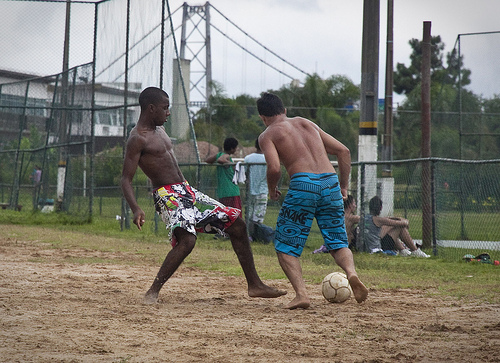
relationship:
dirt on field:
[236, 306, 345, 340] [126, 269, 368, 342]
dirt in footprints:
[236, 306, 345, 340] [273, 285, 321, 328]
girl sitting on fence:
[22, 160, 57, 212] [2, 56, 113, 191]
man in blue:
[243, 44, 366, 324] [265, 165, 354, 267]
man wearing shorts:
[87, 56, 223, 304] [149, 167, 243, 241]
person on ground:
[350, 172, 434, 268] [129, 312, 372, 361]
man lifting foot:
[87, 56, 223, 304] [191, 209, 294, 312]